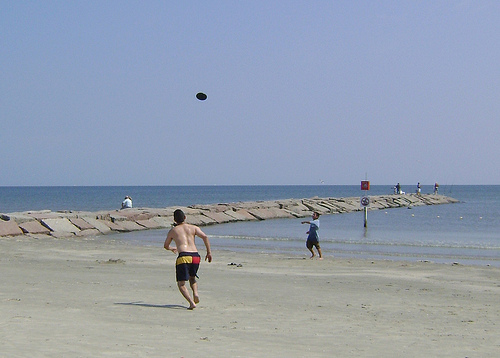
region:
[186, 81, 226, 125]
Frisbee flying in sky.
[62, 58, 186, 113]
Sky is clear and blue.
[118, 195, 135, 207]
Person wearing white shirt.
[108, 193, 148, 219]
Person sitting on rocks near water.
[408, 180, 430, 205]
Person standing on edge of rocks.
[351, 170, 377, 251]
Pole sticking out of water.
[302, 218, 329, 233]
Person wearing blue shirt.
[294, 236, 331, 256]
Person wearing brown shorts.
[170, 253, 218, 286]
Person wearing black, yellow, and red shorts.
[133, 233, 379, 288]
People playing frisbee on beach.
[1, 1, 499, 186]
Cloudless clear blue sky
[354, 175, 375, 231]
Red sign on a mast in the water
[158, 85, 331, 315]
Men playing a game bay the water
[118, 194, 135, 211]
Person sitting near the water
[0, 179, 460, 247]
Simple structure forming a pier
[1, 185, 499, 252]
Clear and calm blue water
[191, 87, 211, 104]
Black gaming object in the air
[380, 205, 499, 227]
Line of white floaters in the water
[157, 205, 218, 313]
Bare chested man running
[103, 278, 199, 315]
Long shadow in the sand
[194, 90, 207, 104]
black frisbee flying in the air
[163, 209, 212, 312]
person wearing black, yellow, and red trunks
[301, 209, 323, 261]
person in blue throwing a frisbee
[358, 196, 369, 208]
red, white, and black sign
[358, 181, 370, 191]
red sign in the water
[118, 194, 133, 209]
person in a white shirt sitting on the rocks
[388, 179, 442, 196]
group of people standing on the rocks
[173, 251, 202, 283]
black shorts on the boy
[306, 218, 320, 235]
blue shorts on the boy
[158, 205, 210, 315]
boy running across the beach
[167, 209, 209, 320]
boy runs on sand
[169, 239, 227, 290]
boy has black shorts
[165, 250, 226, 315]
red and yellow stripe on shorts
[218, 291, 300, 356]
sand is light grey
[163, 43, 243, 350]
boy chases black frisbee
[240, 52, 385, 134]
sky is blue and clear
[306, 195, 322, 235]
man has blue shirt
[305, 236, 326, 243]
man has black pants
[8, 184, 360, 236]
rock wall near water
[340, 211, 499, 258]
water is blue and calm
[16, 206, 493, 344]
a beach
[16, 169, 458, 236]
a stone pier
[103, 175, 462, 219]
people are on the rocks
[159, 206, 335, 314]
two men on the beach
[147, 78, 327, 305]
the men are playing Frisbee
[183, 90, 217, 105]
the Frisbee is in the air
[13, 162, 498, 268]
the rocks extend out into the ocean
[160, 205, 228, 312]
a man runs to catch the Frisbee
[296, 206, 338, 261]
a man by the water has just thrown the frisbee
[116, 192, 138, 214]
a person sits on the rocks facing the water